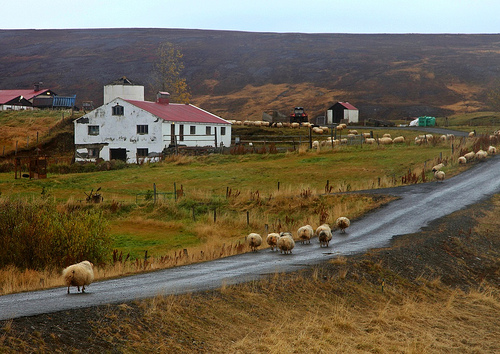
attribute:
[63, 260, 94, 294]
sheep — walking, hairy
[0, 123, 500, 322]
road — paved, wet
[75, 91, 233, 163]
barn — white, large, tall, red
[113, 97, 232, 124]
roof — red, slanted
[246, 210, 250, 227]
post — wooden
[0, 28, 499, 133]
hill — tall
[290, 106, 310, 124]
tractor — large, black, parked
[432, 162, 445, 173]
sheep — grazing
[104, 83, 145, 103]
silo — white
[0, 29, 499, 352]
grass — brown, dry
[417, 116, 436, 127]
container — green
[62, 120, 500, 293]
sheep — walking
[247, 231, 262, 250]
sheep — walking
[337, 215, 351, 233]
sheep — walking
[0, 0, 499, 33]
sky — blue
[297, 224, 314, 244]
sheep — walking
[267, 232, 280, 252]
sheep — walking